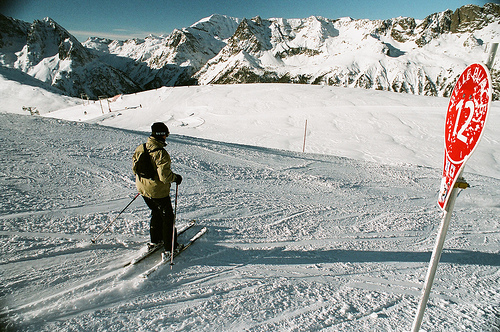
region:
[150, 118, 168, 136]
the man is wearing a cap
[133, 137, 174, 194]
the man is wearing a jacket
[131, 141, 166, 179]
the jacket is tan in color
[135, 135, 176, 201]
the man is wearing a backpack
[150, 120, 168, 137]
the hat is black in color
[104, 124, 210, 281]
the man is skiing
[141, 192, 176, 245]
the man is wearing long pants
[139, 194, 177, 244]
the pants are black in color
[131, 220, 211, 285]
the man is on skis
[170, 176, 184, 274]
the man is holding sky poles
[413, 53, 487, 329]
Red sign on post.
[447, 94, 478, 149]
White number 12 on sign.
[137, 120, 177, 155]
Black hat on head.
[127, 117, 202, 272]
Tan coat on person.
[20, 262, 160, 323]
Tracks in the snow.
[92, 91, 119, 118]
Posts in the snow.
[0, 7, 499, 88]
Mountains in the background.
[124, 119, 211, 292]
Person skiing in the snow.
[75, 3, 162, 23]
Blue gray sky in background.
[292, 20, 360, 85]
Snow on the mountains.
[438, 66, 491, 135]
12 written on ski sign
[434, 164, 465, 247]
ski sign is on a metal pole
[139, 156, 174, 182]
skiier carrying a bag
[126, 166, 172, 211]
ski jacket is yellow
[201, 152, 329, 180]
ground covered in snow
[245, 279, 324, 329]
ski tracks in the snow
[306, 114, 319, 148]
pole in the snow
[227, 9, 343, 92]
snow on the mountains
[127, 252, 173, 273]
snow on the skis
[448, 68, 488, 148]
ski sign is round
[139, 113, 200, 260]
this is a man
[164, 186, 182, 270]
this is a stick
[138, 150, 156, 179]
this is a bag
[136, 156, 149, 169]
the bag is black in color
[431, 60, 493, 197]
this is a signpost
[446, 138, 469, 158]
the signpost is red in color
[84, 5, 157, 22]
this is the sky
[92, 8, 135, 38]
the sky is blue in color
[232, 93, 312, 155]
this is the snow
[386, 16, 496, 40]
this is a mountain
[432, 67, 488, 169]
white and red sign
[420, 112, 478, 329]
sign is on white pole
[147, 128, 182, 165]
person is wearing black hat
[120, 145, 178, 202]
person is wearing brown coat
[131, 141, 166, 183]
person carries black bag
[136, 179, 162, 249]
person is wearing black pants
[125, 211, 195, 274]
person rides on black skis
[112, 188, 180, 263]
person is holding ski poles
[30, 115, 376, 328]
numerous tracks made in snow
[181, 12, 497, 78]
brown and white mountain ahead of man